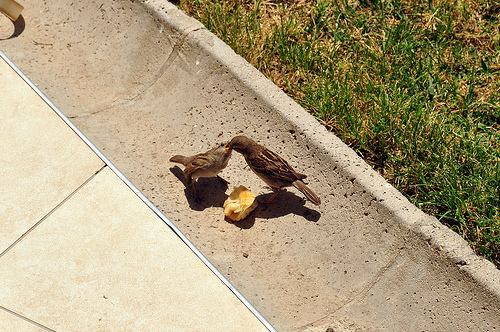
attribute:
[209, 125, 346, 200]
bird —  small, with Wing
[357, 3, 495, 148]
grass — green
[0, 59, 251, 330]
tile — cream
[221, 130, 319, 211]
bird — small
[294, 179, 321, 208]
tail — with  feathers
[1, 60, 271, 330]
tile ground — cream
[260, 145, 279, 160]
feather — brown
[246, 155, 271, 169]
feather — brown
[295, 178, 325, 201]
feather — brown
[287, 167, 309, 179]
feather — brown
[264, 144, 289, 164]
feather — brown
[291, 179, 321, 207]
tail — bird's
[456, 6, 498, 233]
grass — green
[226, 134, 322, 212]
bird —  small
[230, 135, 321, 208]
bird — small, brown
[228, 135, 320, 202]
bird —   small,  brown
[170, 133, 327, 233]
birds — brown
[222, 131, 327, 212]
bird — brown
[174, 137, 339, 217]
bird —  brown,  small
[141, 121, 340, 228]
small birds —  small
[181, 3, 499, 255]
grass — green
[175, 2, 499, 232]
grass — green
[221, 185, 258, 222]
bird — yellow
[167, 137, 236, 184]
bird — small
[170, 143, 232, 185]
bird — small, brown